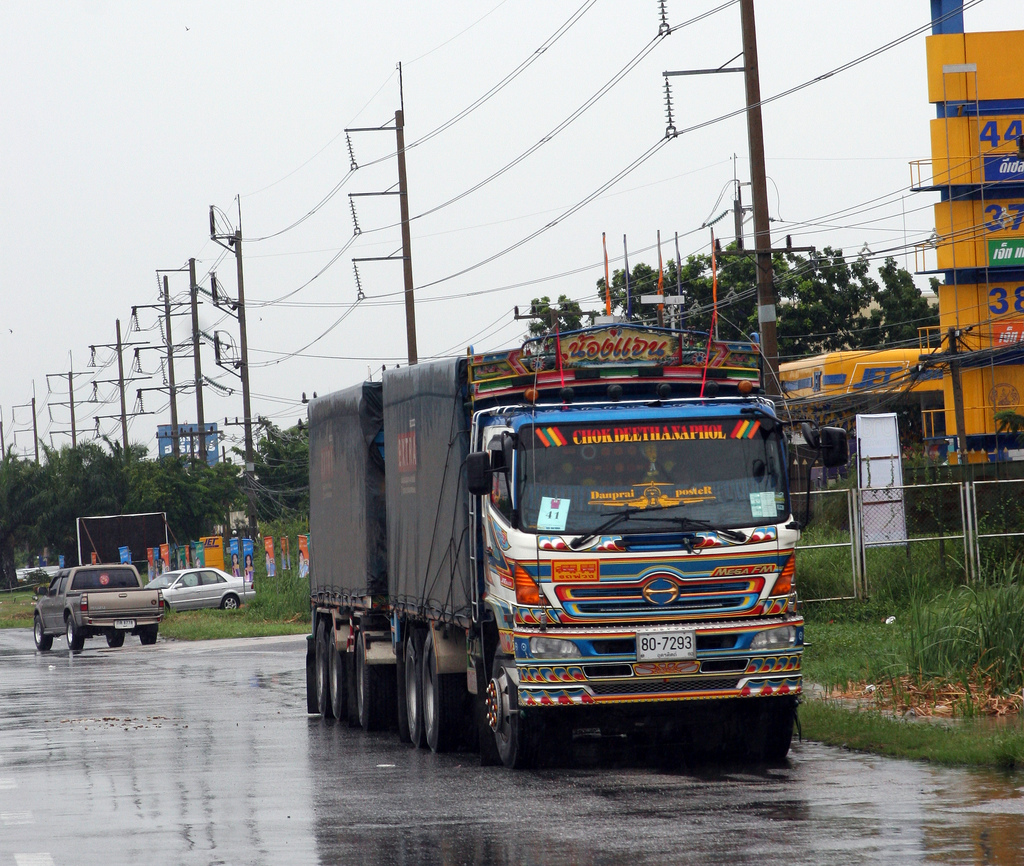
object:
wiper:
[570, 501, 746, 557]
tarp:
[377, 368, 481, 630]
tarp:
[307, 380, 387, 605]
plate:
[115, 619, 136, 628]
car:
[147, 565, 256, 610]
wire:
[239, 132, 404, 248]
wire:
[243, 212, 404, 319]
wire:
[246, 281, 400, 368]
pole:
[348, 61, 424, 365]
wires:
[660, 0, 751, 266]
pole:
[663, 0, 787, 386]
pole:
[206, 200, 269, 546]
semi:
[306, 324, 809, 766]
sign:
[922, 28, 1018, 434]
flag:
[265, 536, 278, 577]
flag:
[195, 542, 205, 569]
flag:
[160, 544, 169, 574]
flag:
[118, 546, 131, 565]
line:
[58, 536, 310, 584]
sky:
[0, 0, 1021, 472]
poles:
[6, 3, 776, 488]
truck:
[32, 564, 157, 650]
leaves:
[528, 246, 949, 369]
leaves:
[159, 488, 174, 501]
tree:
[43, 436, 241, 573]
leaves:
[37, 436, 53, 456]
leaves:
[189, 483, 210, 493]